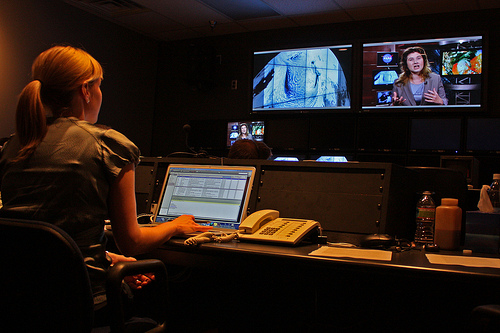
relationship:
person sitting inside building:
[1, 42, 213, 331] [0, 2, 499, 332]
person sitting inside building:
[1, 42, 213, 331] [2, 2, 483, 328]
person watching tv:
[1, 42, 213, 331] [361, 35, 482, 110]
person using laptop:
[1, 42, 213, 331] [138, 160, 257, 230]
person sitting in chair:
[1, 42, 213, 331] [2, 218, 165, 330]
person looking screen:
[1, 47, 213, 326] [251, 52, 484, 102]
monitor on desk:
[153, 165, 236, 225] [144, 213, 479, 309]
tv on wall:
[361, 35, 482, 110] [191, 52, 470, 145]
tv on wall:
[246, 47, 364, 116] [191, 65, 247, 120]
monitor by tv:
[228, 119, 262, 141] [247, 48, 343, 106]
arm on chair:
[131, 251, 170, 283] [3, 221, 151, 331]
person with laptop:
[1, 47, 213, 326] [154, 160, 250, 237]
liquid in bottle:
[437, 234, 455, 251] [433, 197, 464, 257]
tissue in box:
[470, 181, 484, 200] [456, 214, 484, 261]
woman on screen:
[402, 55, 446, 114] [369, 48, 478, 103]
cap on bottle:
[454, 242, 473, 256] [406, 191, 436, 253]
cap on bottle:
[464, 187, 473, 191] [470, 185, 476, 217]